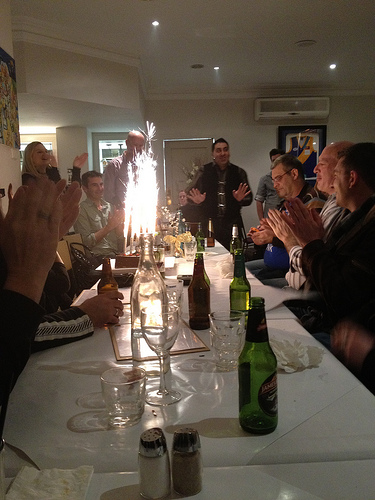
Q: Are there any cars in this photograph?
A: No, there are no cars.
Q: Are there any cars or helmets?
A: No, there are no cars or helmets.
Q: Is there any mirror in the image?
A: No, there are no mirrors.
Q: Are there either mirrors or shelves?
A: No, there are no mirrors or shelves.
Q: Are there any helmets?
A: No, there are no helmets.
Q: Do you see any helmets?
A: No, there are no helmets.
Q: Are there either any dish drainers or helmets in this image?
A: No, there are no helmets or dish drainers.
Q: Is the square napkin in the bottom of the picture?
A: Yes, the napkin is in the bottom of the image.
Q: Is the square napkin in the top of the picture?
A: No, the napkin is in the bottom of the image.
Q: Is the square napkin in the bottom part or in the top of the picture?
A: The napkin is in the bottom of the image.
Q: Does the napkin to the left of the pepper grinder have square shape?
A: Yes, the napkin is square.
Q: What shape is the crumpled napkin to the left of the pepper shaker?
A: The napkin is square.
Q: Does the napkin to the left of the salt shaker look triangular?
A: No, the napkin is square.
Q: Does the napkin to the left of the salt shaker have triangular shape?
A: No, the napkin is square.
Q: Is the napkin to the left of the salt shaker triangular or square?
A: The napkin is square.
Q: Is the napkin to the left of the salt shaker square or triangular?
A: The napkin is square.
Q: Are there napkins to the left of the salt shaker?
A: Yes, there is a napkin to the left of the salt shaker.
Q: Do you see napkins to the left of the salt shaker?
A: Yes, there is a napkin to the left of the salt shaker.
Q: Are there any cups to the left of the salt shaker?
A: No, there is a napkin to the left of the salt shaker.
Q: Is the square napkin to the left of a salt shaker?
A: Yes, the napkin is to the left of a salt shaker.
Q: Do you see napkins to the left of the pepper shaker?
A: Yes, there is a napkin to the left of the pepper shaker.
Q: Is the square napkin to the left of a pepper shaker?
A: Yes, the napkin is to the left of a pepper shaker.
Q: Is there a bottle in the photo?
A: Yes, there is a bottle.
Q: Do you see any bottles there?
A: Yes, there is a bottle.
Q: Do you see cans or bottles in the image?
A: Yes, there is a bottle.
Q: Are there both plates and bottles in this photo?
A: No, there is a bottle but no plates.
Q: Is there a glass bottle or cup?
A: Yes, there is a glass bottle.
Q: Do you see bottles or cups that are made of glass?
A: Yes, the bottle is made of glass.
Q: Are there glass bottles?
A: Yes, there is a bottle that is made of glass.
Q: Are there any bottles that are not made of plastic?
A: Yes, there is a bottle that is made of glass.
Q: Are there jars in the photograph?
A: No, there are no jars.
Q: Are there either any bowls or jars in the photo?
A: No, there are no jars or bowls.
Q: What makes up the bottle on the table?
A: The bottle is made of glass.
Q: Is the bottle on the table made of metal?
A: No, the bottle is made of glass.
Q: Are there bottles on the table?
A: Yes, there is a bottle on the table.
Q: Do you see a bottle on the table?
A: Yes, there is a bottle on the table.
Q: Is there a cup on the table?
A: No, there is a bottle on the table.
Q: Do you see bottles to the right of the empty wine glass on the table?
A: Yes, there is a bottle to the right of the wine glass.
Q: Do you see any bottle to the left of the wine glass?
A: No, the bottle is to the right of the wine glass.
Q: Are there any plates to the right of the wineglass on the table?
A: No, there is a bottle to the right of the wine glass.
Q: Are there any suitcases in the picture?
A: No, there are no suitcases.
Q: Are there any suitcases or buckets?
A: No, there are no suitcases or buckets.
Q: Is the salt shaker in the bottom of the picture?
A: Yes, the salt shaker is in the bottom of the image.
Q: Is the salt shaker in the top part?
A: No, the salt shaker is in the bottom of the image.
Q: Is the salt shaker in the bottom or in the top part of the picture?
A: The salt shaker is in the bottom of the image.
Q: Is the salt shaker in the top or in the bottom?
A: The salt shaker is in the bottom of the image.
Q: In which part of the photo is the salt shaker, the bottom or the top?
A: The salt shaker is in the bottom of the image.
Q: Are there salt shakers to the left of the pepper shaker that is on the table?
A: Yes, there is a salt shaker to the left of the pepper grinder.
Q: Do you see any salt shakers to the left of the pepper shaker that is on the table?
A: Yes, there is a salt shaker to the left of the pepper grinder.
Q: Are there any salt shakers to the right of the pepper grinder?
A: No, the salt shaker is to the left of the pepper grinder.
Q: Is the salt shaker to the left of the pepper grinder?
A: Yes, the salt shaker is to the left of the pepper grinder.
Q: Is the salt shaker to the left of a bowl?
A: No, the salt shaker is to the left of the pepper grinder.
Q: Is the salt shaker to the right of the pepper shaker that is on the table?
A: No, the salt shaker is to the left of the pepper shaker.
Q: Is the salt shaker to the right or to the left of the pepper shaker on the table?
A: The salt shaker is to the left of the pepper shaker.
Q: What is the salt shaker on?
A: The salt shaker is on the table.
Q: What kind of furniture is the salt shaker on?
A: The salt shaker is on the table.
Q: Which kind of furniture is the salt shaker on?
A: The salt shaker is on the table.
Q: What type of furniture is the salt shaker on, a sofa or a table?
A: The salt shaker is on a table.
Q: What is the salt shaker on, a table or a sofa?
A: The salt shaker is on a table.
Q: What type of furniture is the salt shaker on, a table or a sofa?
A: The salt shaker is on a table.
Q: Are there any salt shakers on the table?
A: Yes, there is a salt shaker on the table.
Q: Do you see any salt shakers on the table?
A: Yes, there is a salt shaker on the table.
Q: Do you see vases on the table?
A: No, there is a salt shaker on the table.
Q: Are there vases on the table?
A: No, there is a salt shaker on the table.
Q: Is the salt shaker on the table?
A: Yes, the salt shaker is on the table.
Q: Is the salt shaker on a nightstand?
A: No, the salt shaker is on the table.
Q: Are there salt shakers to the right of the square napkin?
A: Yes, there is a salt shaker to the right of the napkin.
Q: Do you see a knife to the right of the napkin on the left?
A: No, there is a salt shaker to the right of the napkin.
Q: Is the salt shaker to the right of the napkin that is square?
A: Yes, the salt shaker is to the right of the napkin.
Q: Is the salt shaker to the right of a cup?
A: No, the salt shaker is to the right of the napkin.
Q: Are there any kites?
A: No, there are no kites.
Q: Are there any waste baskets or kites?
A: No, there are no kites or waste baskets.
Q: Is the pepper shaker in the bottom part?
A: Yes, the pepper shaker is in the bottom of the image.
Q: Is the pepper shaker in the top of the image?
A: No, the pepper shaker is in the bottom of the image.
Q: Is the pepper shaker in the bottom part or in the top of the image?
A: The pepper shaker is in the bottom of the image.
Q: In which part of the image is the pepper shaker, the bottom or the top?
A: The pepper shaker is in the bottom of the image.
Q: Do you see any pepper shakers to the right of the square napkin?
A: Yes, there is a pepper shaker to the right of the napkin.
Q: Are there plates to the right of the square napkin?
A: No, there is a pepper shaker to the right of the napkin.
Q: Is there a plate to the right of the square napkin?
A: No, there is a pepper shaker to the right of the napkin.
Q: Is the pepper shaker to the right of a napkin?
A: Yes, the pepper shaker is to the right of a napkin.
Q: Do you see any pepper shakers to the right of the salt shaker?
A: Yes, there is a pepper shaker to the right of the salt shaker.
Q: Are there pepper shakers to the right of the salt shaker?
A: Yes, there is a pepper shaker to the right of the salt shaker.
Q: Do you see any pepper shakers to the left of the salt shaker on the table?
A: No, the pepper shaker is to the right of the salt shaker.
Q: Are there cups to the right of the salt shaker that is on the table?
A: No, there is a pepper shaker to the right of the salt shaker.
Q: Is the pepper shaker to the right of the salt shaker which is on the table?
A: Yes, the pepper shaker is to the right of the salt shaker.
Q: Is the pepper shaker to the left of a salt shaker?
A: No, the pepper shaker is to the right of a salt shaker.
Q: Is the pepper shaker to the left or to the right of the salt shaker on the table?
A: The pepper shaker is to the right of the salt shaker.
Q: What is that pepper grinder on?
A: The pepper grinder is on the table.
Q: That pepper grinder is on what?
A: The pepper grinder is on the table.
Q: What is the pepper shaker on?
A: The pepper grinder is on the table.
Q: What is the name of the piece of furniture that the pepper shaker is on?
A: The piece of furniture is a table.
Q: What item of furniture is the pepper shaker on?
A: The pepper shaker is on the table.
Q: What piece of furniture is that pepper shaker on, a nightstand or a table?
A: The pepper shaker is on a table.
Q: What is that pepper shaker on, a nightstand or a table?
A: The pepper shaker is on a table.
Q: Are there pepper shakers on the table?
A: Yes, there is a pepper shaker on the table.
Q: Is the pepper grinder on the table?
A: Yes, the pepper grinder is on the table.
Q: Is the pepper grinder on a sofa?
A: No, the pepper grinder is on the table.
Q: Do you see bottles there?
A: Yes, there is a bottle.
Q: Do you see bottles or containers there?
A: Yes, there is a bottle.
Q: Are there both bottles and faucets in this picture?
A: No, there is a bottle but no faucets.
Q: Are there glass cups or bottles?
A: Yes, there is a glass bottle.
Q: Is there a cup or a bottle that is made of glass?
A: Yes, the bottle is made of glass.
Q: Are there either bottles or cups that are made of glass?
A: Yes, the bottle is made of glass.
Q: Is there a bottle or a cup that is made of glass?
A: Yes, the bottle is made of glass.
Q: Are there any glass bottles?
A: Yes, there is a bottle that is made of glass.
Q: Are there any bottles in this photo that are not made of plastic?
A: Yes, there is a bottle that is made of glass.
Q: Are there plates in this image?
A: No, there are no plates.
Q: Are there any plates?
A: No, there are no plates.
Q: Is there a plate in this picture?
A: No, there are no plates.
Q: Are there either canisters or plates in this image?
A: No, there are no plates or canisters.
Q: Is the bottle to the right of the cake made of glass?
A: Yes, the bottle is made of glass.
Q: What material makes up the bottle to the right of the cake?
A: The bottle is made of glass.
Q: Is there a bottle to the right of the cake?
A: Yes, there is a bottle to the right of the cake.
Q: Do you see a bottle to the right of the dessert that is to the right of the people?
A: Yes, there is a bottle to the right of the cake.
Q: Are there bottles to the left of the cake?
A: No, the bottle is to the right of the cake.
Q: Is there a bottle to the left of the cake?
A: No, the bottle is to the right of the cake.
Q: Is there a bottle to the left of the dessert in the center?
A: No, the bottle is to the right of the cake.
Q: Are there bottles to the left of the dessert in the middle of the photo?
A: No, the bottle is to the right of the cake.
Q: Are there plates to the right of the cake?
A: No, there is a bottle to the right of the cake.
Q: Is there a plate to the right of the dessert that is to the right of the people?
A: No, there is a bottle to the right of the cake.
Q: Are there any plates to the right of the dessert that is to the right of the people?
A: No, there is a bottle to the right of the cake.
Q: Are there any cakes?
A: Yes, there is a cake.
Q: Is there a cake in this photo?
A: Yes, there is a cake.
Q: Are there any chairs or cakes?
A: Yes, there is a cake.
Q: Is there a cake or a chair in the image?
A: Yes, there is a cake.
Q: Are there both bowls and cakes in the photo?
A: No, there is a cake but no bowls.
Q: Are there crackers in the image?
A: No, there are no crackers.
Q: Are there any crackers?
A: No, there are no crackers.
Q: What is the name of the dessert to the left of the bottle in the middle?
A: The dessert is a cake.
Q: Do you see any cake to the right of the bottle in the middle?
A: No, the cake is to the left of the bottle.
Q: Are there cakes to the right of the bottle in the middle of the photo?
A: No, the cake is to the left of the bottle.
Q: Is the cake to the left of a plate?
A: No, the cake is to the left of the bottle.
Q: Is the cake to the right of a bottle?
A: No, the cake is to the left of a bottle.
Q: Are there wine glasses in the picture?
A: Yes, there is a wine glass.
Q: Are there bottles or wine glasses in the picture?
A: Yes, there is a wine glass.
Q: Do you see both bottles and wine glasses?
A: Yes, there are both a wine glass and a bottle.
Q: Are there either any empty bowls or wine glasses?
A: Yes, there is an empty wine glass.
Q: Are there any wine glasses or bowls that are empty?
A: Yes, the wine glass is empty.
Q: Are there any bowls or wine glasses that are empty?
A: Yes, the wine glass is empty.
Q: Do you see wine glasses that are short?
A: Yes, there is a short wine glass.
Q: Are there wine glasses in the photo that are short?
A: Yes, there is a wine glass that is short.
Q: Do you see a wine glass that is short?
A: Yes, there is a wine glass that is short.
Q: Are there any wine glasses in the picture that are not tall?
A: Yes, there is a short wine glass.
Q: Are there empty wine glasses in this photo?
A: Yes, there is an empty wine glass.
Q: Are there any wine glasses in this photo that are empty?
A: Yes, there is a wine glass that is empty.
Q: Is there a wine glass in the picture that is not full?
A: Yes, there is a empty wine glass.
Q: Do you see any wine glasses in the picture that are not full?
A: Yes, there is a empty wine glass.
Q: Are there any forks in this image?
A: No, there are no forks.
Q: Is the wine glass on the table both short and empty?
A: Yes, the wine glass is short and empty.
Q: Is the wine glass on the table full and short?
A: No, the wine glass is short but empty.